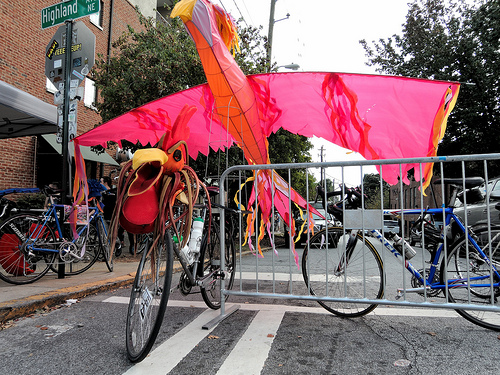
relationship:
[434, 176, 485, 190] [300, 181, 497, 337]
seat on bicycle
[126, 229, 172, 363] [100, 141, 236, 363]
tire of bicycle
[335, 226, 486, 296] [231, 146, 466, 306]
bicycle by rack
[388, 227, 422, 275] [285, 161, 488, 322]
water bottle on bicycle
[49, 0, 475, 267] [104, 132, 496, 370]
kite near bicycles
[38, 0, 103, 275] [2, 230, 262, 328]
street sign on sidewalk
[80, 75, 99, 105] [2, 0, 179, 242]
window on building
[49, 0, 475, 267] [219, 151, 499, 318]
kite near rack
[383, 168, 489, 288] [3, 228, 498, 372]
cars parked on street